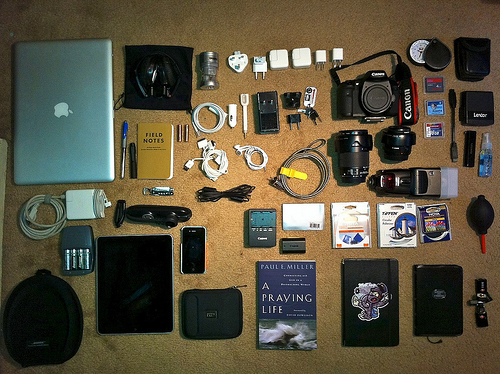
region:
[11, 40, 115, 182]
Apple laptop computer.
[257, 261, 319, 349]
A hardback book.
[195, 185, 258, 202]
Misc cord for an electronic item.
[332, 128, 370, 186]
Canon camera lens.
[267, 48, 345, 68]
Row of white charging blocks.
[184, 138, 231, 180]
White USB charger cable.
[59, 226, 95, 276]
Battery charger with batteries.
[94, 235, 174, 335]
Black tablet.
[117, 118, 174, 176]
Blue pen and notebook.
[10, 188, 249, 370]
Variety of electronics and cords bundled together.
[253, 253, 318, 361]
book on the rug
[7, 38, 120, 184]
laptop on the rug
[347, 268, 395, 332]
sticker on the wallet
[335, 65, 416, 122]
cannon camera on the rug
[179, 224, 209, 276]
cell phone on the rug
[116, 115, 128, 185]
pen on the rug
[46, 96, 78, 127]
apple logog on the laptop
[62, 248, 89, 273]
batteries on the rug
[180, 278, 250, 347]
zippered case on the rug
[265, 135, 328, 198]
cord on the rug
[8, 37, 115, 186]
Grey closed apple laptop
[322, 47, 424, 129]
Cannon camera with a black strap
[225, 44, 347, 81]
Five electrical adapters to the top left of the camera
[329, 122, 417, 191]
Two camera lens below the camera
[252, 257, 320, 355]
Book with the title A Praying Life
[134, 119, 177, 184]
Tan notepad titled field notes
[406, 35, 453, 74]
Compass to the right of the camera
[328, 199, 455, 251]
Three unopened packages below the camera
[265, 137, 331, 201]
Grey cord rolled up with a yellow tie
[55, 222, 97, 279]
Grey container with batteries in it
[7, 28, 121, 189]
laptop computer on brown surface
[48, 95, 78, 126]
logo on a laptop computer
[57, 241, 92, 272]
four batteries in a charger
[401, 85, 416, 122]
white lettering on a strap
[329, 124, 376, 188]
camera lens next to a camera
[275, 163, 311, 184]
yellow strap holding wiring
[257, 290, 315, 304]
white lettering on a blue background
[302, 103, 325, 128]
keys on a key chain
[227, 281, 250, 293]
zipper on a container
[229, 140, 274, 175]
white ear buds next to a white wire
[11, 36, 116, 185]
Apple MaC grey laptop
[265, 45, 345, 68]
Apple products different kinds of charger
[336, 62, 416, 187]
Cannon LCD camera and lenses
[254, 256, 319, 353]
A Praying Life book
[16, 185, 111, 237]
Apple Laptop charger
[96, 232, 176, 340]
Apple iPad in the floor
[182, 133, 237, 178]
iPad white connector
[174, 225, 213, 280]
iPhone in the carpet floor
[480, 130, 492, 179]
spray bottle in the floor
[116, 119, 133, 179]
Blue pen in the floor